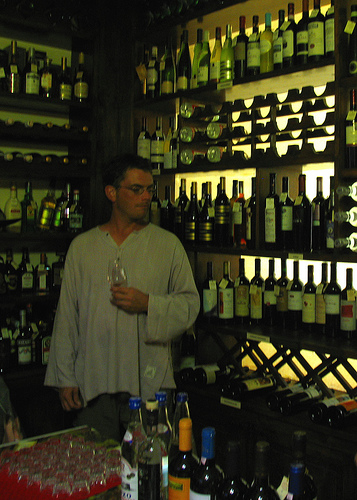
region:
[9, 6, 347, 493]
a scene in a wine storage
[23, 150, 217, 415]
a man standing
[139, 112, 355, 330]
wine bottles on shelves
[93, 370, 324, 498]
wine bottles on table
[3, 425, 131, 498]
glasses on table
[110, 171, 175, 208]
pair of glasses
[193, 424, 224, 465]
the caps are blue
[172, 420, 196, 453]
the cap is orange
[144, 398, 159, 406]
the cap is yellow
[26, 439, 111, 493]
the glasses are empty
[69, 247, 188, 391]
the shirt is tan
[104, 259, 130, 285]
the glass is empty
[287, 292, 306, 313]
the label is white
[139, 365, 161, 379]
the tag is white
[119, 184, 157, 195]
the glasses on the face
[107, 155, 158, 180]
the hair is dark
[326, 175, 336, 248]
wine bottle on shelf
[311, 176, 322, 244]
wine bottle on shelf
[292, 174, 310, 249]
wine bottle on shelf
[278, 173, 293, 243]
wine bottle on shelf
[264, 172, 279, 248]
wine bottle on shelf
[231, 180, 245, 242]
wine bottle on shelf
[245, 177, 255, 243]
wine bottle on shelf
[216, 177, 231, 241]
wine bottle on shelf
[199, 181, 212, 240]
wine bottle on shelf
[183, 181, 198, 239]
wine bottle on shelf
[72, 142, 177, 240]
head of a man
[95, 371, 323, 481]
many bottles grouped together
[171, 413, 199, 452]
yellow top of bottle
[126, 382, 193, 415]
three blue tops on bottles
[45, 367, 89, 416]
hand of the man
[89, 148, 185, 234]
man looking to the left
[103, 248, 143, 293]
glass in man's hand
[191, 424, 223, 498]
a bottle of wine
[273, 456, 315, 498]
a bottle of wine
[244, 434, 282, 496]
a bottle of wine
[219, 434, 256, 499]
a bottle of wine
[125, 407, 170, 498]
a bottle of wine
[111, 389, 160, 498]
a bottle of wine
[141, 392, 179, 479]
a bottle of wine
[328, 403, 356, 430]
a bottle on a shelf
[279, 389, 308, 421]
a bottle on a shelf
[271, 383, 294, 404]
a bottle on a shelf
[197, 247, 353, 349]
bottles of liquor on a shelf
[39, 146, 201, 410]
man holding an empty glass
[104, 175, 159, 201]
glasses on a face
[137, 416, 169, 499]
a bottle of booze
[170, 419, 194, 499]
a bottle of booze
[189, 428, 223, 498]
a bottle of booze